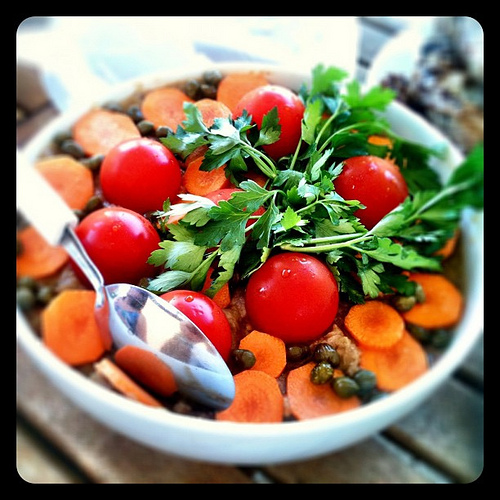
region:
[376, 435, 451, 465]
faded brown color on surface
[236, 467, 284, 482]
space between brown board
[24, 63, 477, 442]
deep white bowl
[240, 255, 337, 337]
large round juicy grape tomato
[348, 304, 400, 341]
slice of orange carrot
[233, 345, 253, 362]
tiny green nut slice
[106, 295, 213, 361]
reflection on back of spoon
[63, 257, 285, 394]
mouth of silver spoon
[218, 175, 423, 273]
bunch of green parsley leaves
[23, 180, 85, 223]
white handle on spoon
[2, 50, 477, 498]
the fruits are in a bowl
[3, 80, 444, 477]
the carrots are chopped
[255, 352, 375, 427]
the carrots are orange in colour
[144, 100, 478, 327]
the vegetable is green in colour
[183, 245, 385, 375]
the fruit is red in colour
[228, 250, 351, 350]
the fruits are ripe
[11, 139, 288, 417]
the spoon is in the bowl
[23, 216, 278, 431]
the spoon is silver in colour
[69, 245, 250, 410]
the spoon is reflecting some people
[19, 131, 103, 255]
the spoon has a white handle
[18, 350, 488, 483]
a wooden table that the bowl is sitting on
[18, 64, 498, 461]
a white bowl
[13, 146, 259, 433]
a spoon with a white handle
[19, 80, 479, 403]
a white bowl of food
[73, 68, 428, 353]
small round red tomatoes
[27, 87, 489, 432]
round, sliced, orange carrots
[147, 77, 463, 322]
parsley on top of the other food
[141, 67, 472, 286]
a parsley garnish on the bowl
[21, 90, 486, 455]
a bowl of tomatoes and carrots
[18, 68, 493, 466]
a bowl of food with a spoon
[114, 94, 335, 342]
red tomatoes in bowl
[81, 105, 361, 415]
orange carrots in bowl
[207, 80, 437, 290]
green and leafy vegetable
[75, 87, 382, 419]
vegetables in white bowl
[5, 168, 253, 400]
steel spoon in bowl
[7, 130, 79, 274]
white handle on spoon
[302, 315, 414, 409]
small legumes in bowl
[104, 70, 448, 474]
bowl on brown table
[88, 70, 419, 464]
vegetables in salad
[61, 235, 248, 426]
reflection is shown in spoon